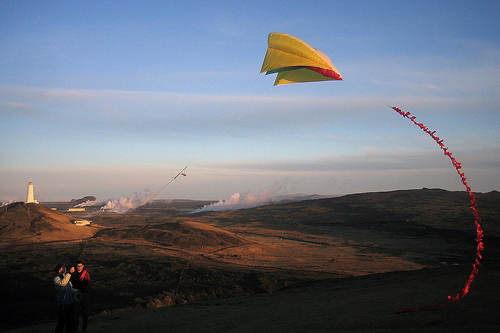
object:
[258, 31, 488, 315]
kite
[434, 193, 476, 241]
ground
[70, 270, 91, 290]
jacket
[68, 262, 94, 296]
man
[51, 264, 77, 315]
man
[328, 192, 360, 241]
ground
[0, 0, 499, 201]
clouds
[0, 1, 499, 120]
air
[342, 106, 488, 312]
tassel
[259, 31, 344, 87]
yellow kite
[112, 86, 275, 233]
line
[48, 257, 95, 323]
family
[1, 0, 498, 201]
sky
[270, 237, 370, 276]
ground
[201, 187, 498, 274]
mountain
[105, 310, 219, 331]
ground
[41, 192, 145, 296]
ground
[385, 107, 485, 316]
kite tail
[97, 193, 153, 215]
fog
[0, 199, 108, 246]
hill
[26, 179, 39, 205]
lighthouse